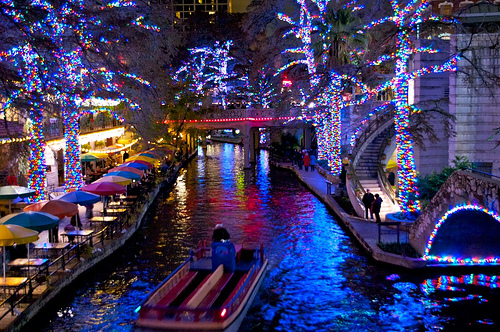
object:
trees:
[0, 0, 159, 200]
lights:
[60, 52, 81, 71]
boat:
[128, 240, 269, 331]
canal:
[11, 140, 500, 332]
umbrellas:
[82, 180, 129, 196]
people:
[369, 193, 387, 221]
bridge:
[155, 107, 305, 170]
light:
[158, 118, 296, 122]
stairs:
[345, 105, 403, 215]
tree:
[331, 0, 457, 214]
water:
[9, 139, 497, 331]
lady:
[301, 152, 309, 172]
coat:
[302, 154, 310, 165]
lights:
[395, 57, 404, 68]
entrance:
[406, 168, 499, 271]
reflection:
[171, 169, 193, 218]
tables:
[8, 258, 51, 280]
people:
[293, 147, 303, 168]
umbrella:
[0, 223, 38, 248]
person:
[212, 224, 228, 243]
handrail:
[265, 147, 297, 170]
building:
[331, 0, 500, 269]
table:
[0, 276, 28, 297]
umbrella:
[2, 211, 63, 232]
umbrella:
[20, 198, 79, 220]